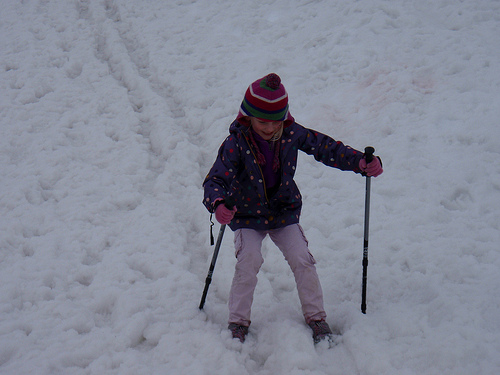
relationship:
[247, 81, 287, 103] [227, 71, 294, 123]
stripe on hat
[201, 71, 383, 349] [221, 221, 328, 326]
child has pants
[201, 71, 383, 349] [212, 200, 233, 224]
child has gloves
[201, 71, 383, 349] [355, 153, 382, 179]
child has gloves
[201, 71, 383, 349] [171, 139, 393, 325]
child holds poles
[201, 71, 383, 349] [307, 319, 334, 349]
child has shoe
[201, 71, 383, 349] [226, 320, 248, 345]
child has shoe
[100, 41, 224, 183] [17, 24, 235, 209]
tracks in snow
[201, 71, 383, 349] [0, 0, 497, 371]
child looks at snow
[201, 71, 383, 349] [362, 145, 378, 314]
child holds pole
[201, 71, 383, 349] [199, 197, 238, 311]
child holds poles